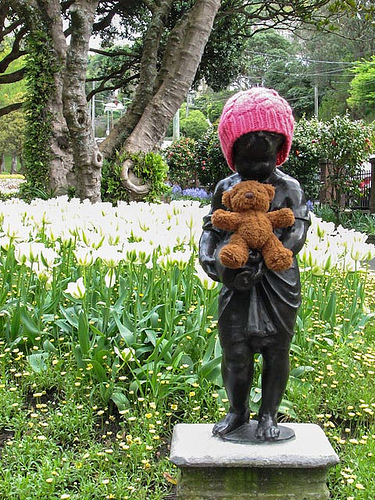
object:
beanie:
[217, 85, 296, 172]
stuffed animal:
[210, 179, 296, 273]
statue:
[194, 82, 315, 448]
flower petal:
[66, 277, 85, 298]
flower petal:
[99, 247, 122, 266]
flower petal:
[39, 249, 58, 265]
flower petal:
[73, 249, 97, 265]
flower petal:
[24, 244, 38, 260]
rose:
[201, 167, 206, 172]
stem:
[349, 269, 361, 324]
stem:
[75, 314, 91, 361]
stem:
[133, 286, 141, 345]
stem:
[15, 269, 22, 348]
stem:
[104, 290, 113, 347]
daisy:
[349, 244, 366, 264]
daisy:
[318, 250, 337, 276]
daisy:
[123, 245, 139, 263]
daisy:
[172, 247, 191, 273]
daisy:
[159, 236, 180, 250]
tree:
[56, 0, 102, 201]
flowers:
[5, 215, 23, 235]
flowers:
[84, 227, 105, 247]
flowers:
[139, 212, 156, 230]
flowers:
[117, 221, 135, 235]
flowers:
[183, 215, 199, 228]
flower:
[196, 190, 207, 199]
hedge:
[345, 169, 373, 213]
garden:
[0, 190, 374, 500]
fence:
[346, 169, 373, 208]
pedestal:
[167, 422, 339, 499]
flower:
[178, 232, 192, 244]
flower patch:
[0, 195, 375, 420]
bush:
[169, 139, 200, 186]